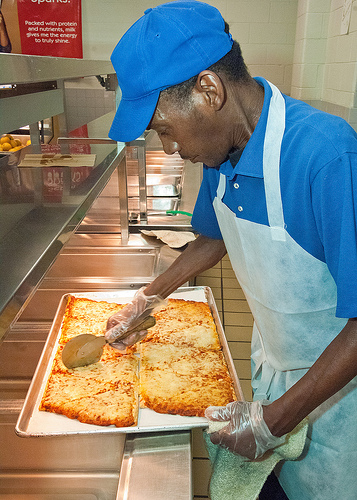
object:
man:
[106, 0, 356, 500]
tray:
[13, 285, 246, 438]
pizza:
[38, 294, 237, 427]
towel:
[203, 428, 309, 499]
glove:
[205, 400, 288, 461]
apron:
[213, 80, 357, 500]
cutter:
[62, 315, 156, 369]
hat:
[108, 1, 233, 143]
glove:
[105, 286, 168, 352]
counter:
[0, 150, 193, 500]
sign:
[17, 1, 83, 61]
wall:
[2, 1, 357, 143]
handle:
[104, 315, 157, 346]